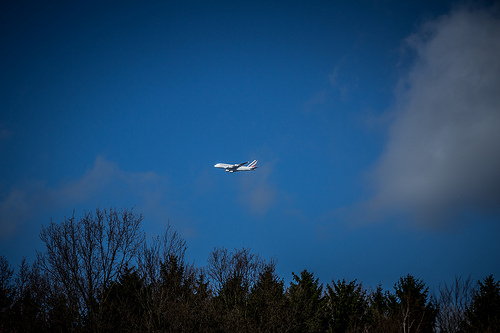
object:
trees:
[385, 272, 436, 333]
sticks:
[39, 206, 142, 308]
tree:
[36, 203, 145, 331]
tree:
[242, 263, 291, 331]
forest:
[2, 205, 497, 333]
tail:
[248, 159, 258, 167]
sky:
[0, 2, 496, 286]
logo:
[249, 161, 256, 168]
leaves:
[281, 309, 317, 331]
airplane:
[214, 159, 259, 173]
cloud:
[374, 3, 500, 216]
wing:
[234, 162, 248, 168]